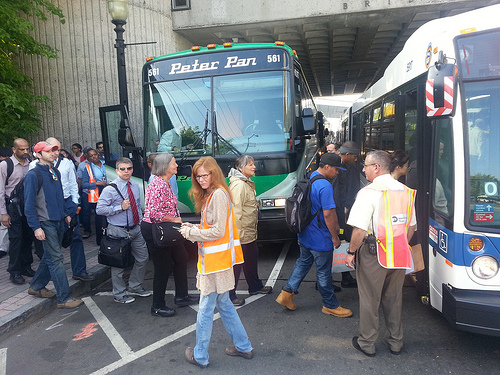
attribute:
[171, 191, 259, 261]
jacket — reflective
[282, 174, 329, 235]
backpack — black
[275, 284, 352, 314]
boots — brown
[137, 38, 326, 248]
bus — blue, white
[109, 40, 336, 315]
bus — green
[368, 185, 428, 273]
vest — red, reflective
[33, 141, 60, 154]
hat — red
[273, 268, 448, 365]
boots — brown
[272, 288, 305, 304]
boot — brown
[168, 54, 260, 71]
name — Peter Pan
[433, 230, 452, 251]
handicap symbol — blue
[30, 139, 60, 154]
baseball cap — red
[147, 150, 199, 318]
lady — older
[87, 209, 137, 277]
briefcase — black, soft side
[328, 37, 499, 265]
bus — white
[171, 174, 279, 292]
vest — reflective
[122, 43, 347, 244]
bus — green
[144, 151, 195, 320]
older woman — cuacasian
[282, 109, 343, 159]
mirror — rearview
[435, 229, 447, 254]
handicap sticker — blue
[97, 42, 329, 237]
bus — green, black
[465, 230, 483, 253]
turn signal — orange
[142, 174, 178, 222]
shirt — colorful